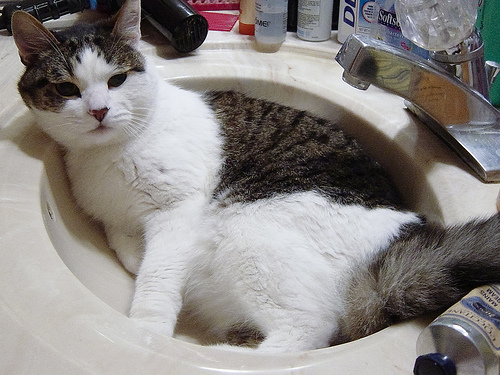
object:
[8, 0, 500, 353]
cat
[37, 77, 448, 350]
sink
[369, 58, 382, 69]
chrome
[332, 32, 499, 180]
faucet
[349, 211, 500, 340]
tail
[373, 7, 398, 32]
pump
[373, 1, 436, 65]
soap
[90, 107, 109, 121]
nose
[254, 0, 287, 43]
tube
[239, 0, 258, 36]
cream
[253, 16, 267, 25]
black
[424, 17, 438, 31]
plastic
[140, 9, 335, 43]
counter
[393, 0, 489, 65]
knob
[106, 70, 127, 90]
eye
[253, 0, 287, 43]
bottle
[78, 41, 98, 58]
fur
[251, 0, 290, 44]
products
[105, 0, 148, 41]
ears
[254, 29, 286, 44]
bottom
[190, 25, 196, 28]
vents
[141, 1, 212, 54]
dryer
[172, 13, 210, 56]
knozzle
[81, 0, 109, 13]
switch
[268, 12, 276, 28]
silver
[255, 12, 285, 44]
liquid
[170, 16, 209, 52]
end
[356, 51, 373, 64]
reflection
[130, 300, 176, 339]
paw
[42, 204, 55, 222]
hole